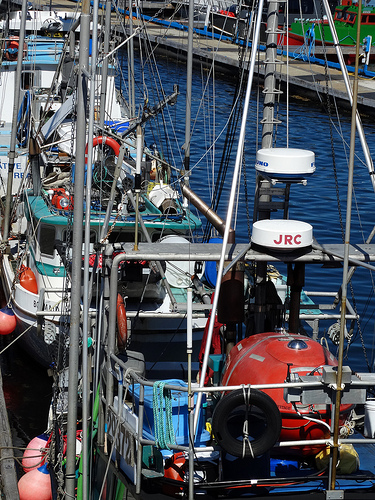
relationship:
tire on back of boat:
[211, 387, 282, 460] [16, 0, 375, 499]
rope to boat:
[153, 380, 175, 451] [63, 234, 342, 497]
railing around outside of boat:
[100, 342, 375, 494] [47, 237, 363, 484]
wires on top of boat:
[95, 10, 300, 195] [47, 237, 363, 484]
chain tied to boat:
[45, 212, 77, 484] [36, 239, 361, 464]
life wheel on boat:
[88, 134, 129, 175] [16, 0, 375, 499]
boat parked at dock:
[16, 0, 375, 499] [0, 392, 17, 497]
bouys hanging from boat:
[0, 0, 375, 499] [47, 237, 363, 484]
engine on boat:
[215, 334, 339, 457] [47, 237, 363, 484]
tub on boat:
[131, 374, 200, 436] [54, 252, 324, 498]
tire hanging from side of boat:
[210, 389, 282, 460] [16, 0, 375, 499]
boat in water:
[3, 150, 219, 337] [137, 97, 361, 310]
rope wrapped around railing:
[150, 378, 173, 449] [99, 351, 217, 494]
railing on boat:
[100, 342, 362, 487] [71, 269, 358, 498]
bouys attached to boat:
[0, 0, 375, 499] [36, 239, 361, 464]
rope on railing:
[153, 380, 175, 451] [100, 342, 375, 494]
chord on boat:
[209, 385, 284, 460] [81, 239, 358, 494]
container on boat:
[130, 377, 201, 442] [63, 234, 342, 497]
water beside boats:
[105, 37, 361, 375] [4, 2, 361, 494]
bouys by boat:
[18, 431, 57, 495] [47, 237, 363, 484]